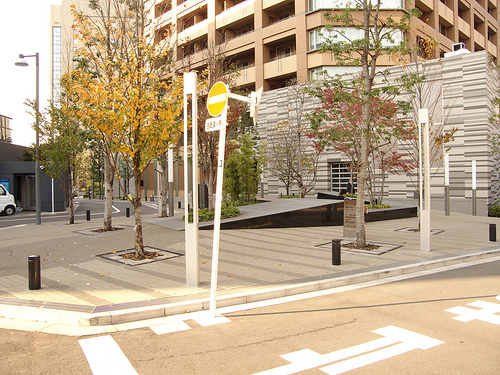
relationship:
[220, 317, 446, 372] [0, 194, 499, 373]
paint on floor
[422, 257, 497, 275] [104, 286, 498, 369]
shadow on street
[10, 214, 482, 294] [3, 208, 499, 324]
shadow on sidewalk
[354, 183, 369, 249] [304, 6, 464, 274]
trunk of tree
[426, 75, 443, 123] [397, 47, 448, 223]
branches on tree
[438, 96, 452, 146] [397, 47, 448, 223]
branches on tree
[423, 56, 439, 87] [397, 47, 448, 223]
branches on tree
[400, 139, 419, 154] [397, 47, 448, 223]
branches on tree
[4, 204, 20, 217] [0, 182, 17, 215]
wheel on car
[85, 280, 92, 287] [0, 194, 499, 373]
leaf on floor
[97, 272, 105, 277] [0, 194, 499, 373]
leaf on floor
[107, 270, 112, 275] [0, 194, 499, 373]
leaf on floor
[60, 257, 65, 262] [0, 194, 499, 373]
leaf on floor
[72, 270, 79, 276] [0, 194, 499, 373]
leaf on floor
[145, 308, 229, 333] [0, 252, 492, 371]
line on floor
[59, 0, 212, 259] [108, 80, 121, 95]
tree has leaves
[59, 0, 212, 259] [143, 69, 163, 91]
tree has leaves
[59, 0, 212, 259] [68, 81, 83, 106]
tree has leaves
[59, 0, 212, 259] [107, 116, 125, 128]
tree has leaves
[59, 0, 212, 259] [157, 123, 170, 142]
tree has leaves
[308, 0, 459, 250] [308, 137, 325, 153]
tree has flower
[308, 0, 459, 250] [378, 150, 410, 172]
tree has flower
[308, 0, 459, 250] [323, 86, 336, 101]
tree has flower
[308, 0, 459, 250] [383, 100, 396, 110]
tree has flower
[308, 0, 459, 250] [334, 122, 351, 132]
tree has flower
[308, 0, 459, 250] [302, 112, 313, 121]
tree has leaf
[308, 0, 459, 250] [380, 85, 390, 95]
tree has leaf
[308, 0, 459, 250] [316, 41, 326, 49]
tree has leaf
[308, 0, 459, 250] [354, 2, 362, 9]
tree has leaf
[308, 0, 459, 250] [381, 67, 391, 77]
tree has leaf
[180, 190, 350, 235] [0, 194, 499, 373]
ramp in middle of floor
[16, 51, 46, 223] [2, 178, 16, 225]
light near car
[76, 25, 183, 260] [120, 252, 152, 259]
tree planted hole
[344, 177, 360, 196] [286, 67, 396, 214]
man walking out of building lobby